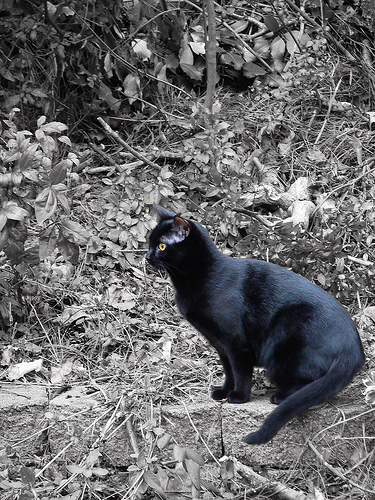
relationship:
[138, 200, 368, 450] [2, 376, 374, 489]
cat on top of wall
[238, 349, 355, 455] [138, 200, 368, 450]
tail of cat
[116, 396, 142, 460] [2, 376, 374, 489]
branches over wall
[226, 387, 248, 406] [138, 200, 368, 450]
paw of cat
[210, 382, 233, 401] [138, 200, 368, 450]
paw of cat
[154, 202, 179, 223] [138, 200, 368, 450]
ear of cat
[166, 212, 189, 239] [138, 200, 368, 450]
ear of cat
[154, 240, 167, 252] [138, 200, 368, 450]
eye of cat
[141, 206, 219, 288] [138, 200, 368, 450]
head of cat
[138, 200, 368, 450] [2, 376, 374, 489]
cat on wall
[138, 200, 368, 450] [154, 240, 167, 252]
cat with eye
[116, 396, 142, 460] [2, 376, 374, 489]
branches in front of wall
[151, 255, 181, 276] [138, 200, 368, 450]
whiskers of cat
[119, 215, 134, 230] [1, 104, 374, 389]
leaves on ground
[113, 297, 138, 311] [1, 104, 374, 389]
leaves on ground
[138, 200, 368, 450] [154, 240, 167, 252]
cat has eye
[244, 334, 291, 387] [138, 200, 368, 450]
stomach of cat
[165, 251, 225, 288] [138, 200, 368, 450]
neck of cat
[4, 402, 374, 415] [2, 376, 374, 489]
edge of wall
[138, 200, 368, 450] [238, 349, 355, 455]
cat has tail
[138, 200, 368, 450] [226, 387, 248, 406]
cat has paw